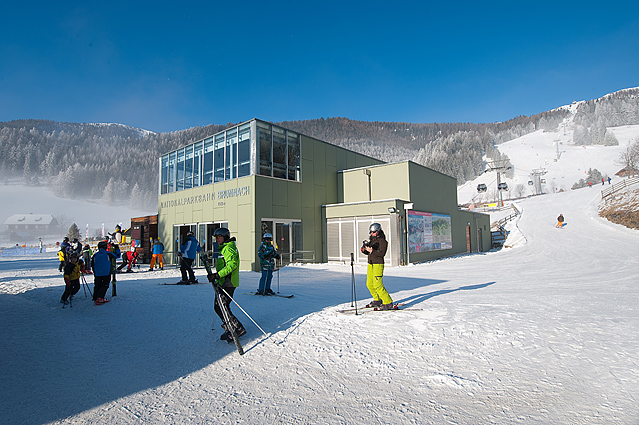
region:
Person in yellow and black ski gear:
[362, 221, 403, 317]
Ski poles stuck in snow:
[346, 248, 360, 315]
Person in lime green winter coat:
[201, 224, 270, 358]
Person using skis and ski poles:
[253, 228, 294, 305]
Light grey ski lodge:
[155, 116, 495, 269]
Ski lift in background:
[477, 158, 520, 210]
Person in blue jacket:
[88, 240, 123, 308]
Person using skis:
[55, 248, 87, 312]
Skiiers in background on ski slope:
[582, 174, 617, 192]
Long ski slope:
[491, 172, 638, 421]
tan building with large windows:
[166, 110, 470, 285]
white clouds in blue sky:
[500, 10, 547, 46]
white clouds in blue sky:
[452, 34, 501, 90]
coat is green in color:
[194, 226, 250, 292]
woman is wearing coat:
[204, 227, 247, 289]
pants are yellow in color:
[362, 253, 411, 310]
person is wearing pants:
[353, 270, 397, 307]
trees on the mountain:
[4, 94, 152, 214]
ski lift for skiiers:
[477, 161, 520, 209]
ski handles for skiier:
[342, 249, 360, 318]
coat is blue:
[90, 245, 119, 278]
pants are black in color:
[98, 273, 109, 306]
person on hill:
[553, 208, 573, 233]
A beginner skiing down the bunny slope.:
[541, 207, 580, 236]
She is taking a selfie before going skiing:
[334, 219, 409, 319]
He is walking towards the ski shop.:
[186, 224, 276, 362]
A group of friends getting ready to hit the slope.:
[53, 232, 131, 312]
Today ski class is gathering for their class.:
[39, 101, 491, 365]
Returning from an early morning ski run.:
[541, 208, 578, 234]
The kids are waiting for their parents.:
[52, 234, 126, 306]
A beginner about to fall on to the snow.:
[118, 243, 147, 280]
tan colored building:
[159, 124, 494, 291]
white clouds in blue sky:
[336, 45, 386, 102]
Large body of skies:
[48, 11, 197, 92]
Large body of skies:
[49, 19, 223, 102]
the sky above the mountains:
[6, 22, 602, 105]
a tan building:
[162, 126, 477, 249]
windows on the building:
[161, 129, 307, 178]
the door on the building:
[277, 222, 292, 255]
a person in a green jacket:
[212, 225, 245, 331]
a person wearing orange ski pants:
[363, 223, 395, 313]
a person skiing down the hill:
[554, 212, 567, 226]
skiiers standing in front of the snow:
[47, 223, 230, 298]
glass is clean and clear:
[235, 138, 248, 163]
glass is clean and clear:
[259, 127, 272, 162]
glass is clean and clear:
[273, 133, 283, 166]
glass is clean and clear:
[283, 133, 299, 168]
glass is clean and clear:
[210, 143, 223, 171]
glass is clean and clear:
[182, 158, 193, 176]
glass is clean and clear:
[169, 160, 176, 179]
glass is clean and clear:
[179, 157, 188, 176]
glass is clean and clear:
[201, 172, 212, 182]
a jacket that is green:
[197, 242, 240, 289]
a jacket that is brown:
[372, 240, 395, 263]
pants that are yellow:
[361, 258, 395, 309]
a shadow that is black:
[52, 295, 194, 411]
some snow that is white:
[253, 324, 422, 422]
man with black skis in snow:
[209, 220, 263, 356]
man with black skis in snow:
[339, 222, 401, 322]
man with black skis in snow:
[180, 214, 209, 279]